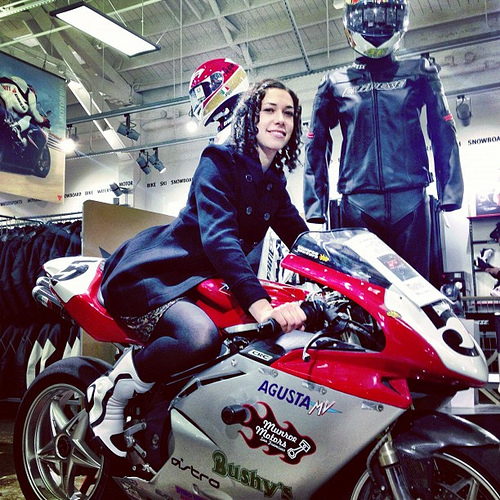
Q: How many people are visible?
A: One.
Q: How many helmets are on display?
A: Two.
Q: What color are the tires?
A: Black.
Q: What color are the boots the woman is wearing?
A: White.